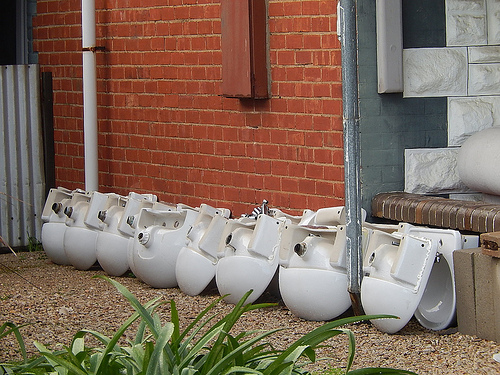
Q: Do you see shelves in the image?
A: No, there are no shelves.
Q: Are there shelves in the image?
A: No, there are no shelves.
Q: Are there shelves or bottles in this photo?
A: No, there are no shelves or bottles.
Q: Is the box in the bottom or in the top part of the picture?
A: The box is in the top of the image.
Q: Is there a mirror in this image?
A: No, there are no mirrors.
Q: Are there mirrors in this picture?
A: No, there are no mirrors.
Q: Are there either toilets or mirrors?
A: No, there are no mirrors or toilets.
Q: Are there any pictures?
A: No, there are no pictures.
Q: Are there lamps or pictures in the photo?
A: No, there are no pictures or lamps.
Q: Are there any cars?
A: No, there are no cars.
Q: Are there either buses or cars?
A: No, there are no cars or buses.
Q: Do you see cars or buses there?
A: No, there are no cars or buses.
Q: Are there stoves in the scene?
A: No, there are no stoves.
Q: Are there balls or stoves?
A: No, there are no stoves or balls.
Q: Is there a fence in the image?
A: Yes, there is a fence.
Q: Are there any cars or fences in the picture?
A: Yes, there is a fence.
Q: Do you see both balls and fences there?
A: No, there is a fence but no balls.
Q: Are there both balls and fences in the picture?
A: No, there is a fence but no balls.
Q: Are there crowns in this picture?
A: No, there are no crowns.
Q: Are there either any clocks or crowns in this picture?
A: No, there are no crowns or clocks.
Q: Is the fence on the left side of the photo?
A: Yes, the fence is on the left of the image.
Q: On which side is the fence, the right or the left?
A: The fence is on the left of the image.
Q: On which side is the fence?
A: The fence is on the left of the image.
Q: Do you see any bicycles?
A: No, there are no bicycles.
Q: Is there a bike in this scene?
A: No, there are no bikes.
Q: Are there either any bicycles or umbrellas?
A: No, there are no bicycles or umbrellas.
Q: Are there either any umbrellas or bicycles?
A: No, there are no bicycles or umbrellas.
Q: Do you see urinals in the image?
A: No, there are no urinals.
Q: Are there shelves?
A: No, there are no shelves.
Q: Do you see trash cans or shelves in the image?
A: No, there are no shelves or trash cans.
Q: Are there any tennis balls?
A: No, there are no tennis balls.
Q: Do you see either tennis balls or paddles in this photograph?
A: No, there are no tennis balls or paddles.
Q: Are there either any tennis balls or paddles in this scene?
A: No, there are no tennis balls or paddles.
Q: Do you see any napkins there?
A: No, there are no napkins.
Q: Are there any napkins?
A: No, there are no napkins.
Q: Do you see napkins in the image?
A: No, there are no napkins.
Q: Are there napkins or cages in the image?
A: No, there are no napkins or cages.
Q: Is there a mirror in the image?
A: No, there are no mirrors.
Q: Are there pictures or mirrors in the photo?
A: No, there are no mirrors or pictures.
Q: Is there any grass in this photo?
A: Yes, there is grass.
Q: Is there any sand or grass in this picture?
A: Yes, there is grass.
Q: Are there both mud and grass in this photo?
A: No, there is grass but no mud.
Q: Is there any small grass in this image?
A: Yes, there is small grass.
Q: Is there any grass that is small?
A: Yes, there is grass that is small.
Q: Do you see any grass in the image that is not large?
A: Yes, there is small grass.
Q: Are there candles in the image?
A: No, there are no candles.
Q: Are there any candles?
A: No, there are no candles.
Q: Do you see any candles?
A: No, there are no candles.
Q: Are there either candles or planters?
A: No, there are no candles or planters.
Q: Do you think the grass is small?
A: Yes, the grass is small.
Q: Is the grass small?
A: Yes, the grass is small.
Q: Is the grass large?
A: No, the grass is small.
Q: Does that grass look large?
A: No, the grass is small.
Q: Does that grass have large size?
A: No, the grass is small.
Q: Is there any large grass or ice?
A: No, there is grass but it is small.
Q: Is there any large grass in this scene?
A: No, there is grass but it is small.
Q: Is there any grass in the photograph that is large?
A: No, there is grass but it is small.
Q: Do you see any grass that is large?
A: No, there is grass but it is small.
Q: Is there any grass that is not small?
A: No, there is grass but it is small.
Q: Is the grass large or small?
A: The grass is small.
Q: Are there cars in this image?
A: No, there are no cars.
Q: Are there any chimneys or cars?
A: No, there are no cars or chimneys.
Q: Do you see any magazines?
A: No, there are no magazines.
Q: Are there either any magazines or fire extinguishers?
A: No, there are no magazines or fire extinguishers.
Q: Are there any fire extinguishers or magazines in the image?
A: No, there are no magazines or fire extinguishers.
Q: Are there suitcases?
A: No, there are no suitcases.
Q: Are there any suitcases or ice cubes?
A: No, there are no suitcases or ice cubes.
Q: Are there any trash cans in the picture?
A: No, there are no trash cans.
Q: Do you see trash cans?
A: No, there are no trash cans.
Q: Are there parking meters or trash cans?
A: No, there are no trash cans or parking meters.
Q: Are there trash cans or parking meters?
A: No, there are no trash cans or parking meters.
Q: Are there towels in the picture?
A: No, there are no towels.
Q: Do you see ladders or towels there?
A: No, there are no towels or ladders.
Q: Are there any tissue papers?
A: No, there are no tissue papers.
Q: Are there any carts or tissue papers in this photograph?
A: No, there are no tissue papers or carts.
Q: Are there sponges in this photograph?
A: No, there are no sponges.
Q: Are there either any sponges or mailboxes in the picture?
A: No, there are no sponges or mailboxes.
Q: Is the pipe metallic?
A: Yes, the pipe is metallic.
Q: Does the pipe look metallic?
A: Yes, the pipe is metallic.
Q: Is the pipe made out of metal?
A: Yes, the pipe is made of metal.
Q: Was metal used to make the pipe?
A: Yes, the pipe is made of metal.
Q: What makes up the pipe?
A: The pipe is made of metal.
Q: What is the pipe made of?
A: The pipe is made of metal.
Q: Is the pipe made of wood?
A: No, the pipe is made of metal.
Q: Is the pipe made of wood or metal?
A: The pipe is made of metal.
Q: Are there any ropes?
A: No, there are no ropes.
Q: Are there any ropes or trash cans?
A: No, there are no ropes or trash cans.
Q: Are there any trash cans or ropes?
A: No, there are no ropes or trash cans.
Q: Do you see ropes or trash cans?
A: No, there are no ropes or trash cans.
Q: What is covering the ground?
A: The gravel is covering the ground.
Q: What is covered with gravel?
A: The ground is covered with gravel.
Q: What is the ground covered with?
A: The ground is covered with gravel.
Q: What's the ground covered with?
A: The ground is covered with gravel.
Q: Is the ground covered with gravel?
A: Yes, the ground is covered with gravel.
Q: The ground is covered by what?
A: The ground is covered by the gravel.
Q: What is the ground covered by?
A: The ground is covered by the gravel.